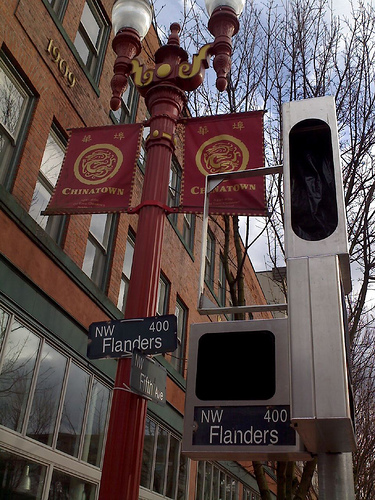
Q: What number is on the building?
A: 1909.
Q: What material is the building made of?
A: Brick.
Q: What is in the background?
A: A tree.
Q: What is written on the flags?
A: Chinatown.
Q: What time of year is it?
A: Winter.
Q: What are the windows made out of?
A: Glass.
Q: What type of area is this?
A: A city.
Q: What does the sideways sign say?
A: NW Fifth Ave.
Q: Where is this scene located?
A: Street in Chinatown.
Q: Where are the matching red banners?
A: Upper part of light post.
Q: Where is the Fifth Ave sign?
A: Lower right side of light post.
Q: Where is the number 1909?
A: Upper left of the brick building.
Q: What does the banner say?
A: Chinatown.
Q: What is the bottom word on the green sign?
A: Flanders.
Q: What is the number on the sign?
A: 400.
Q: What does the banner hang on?
A: Pole.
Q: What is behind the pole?
A: Buildings.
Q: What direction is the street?
A: NW.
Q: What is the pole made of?
A: Metal.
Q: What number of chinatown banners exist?
A: 2.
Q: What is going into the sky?
A: Trees.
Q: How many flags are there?
A: Two.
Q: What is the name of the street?
A: NW Flanders.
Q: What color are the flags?
A: Red.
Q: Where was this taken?
A: Chinatown.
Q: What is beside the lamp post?
A: Traffic lights.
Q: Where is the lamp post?
A: To the left of the traffic light.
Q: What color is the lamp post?
A: Red.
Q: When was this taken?
A: Daytime.